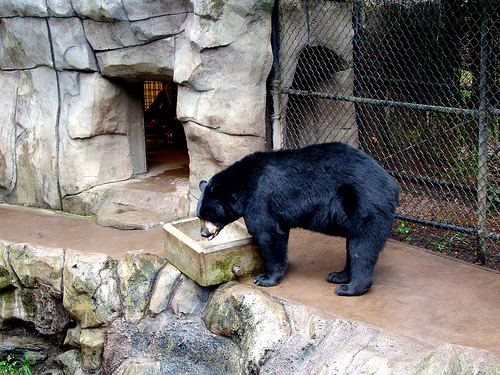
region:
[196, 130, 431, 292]
the bear is black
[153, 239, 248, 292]
the bin is white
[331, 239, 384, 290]
the bear has hind legs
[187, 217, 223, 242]
the bear has a nose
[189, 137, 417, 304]
the bear coat is shiney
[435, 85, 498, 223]
the fence is metal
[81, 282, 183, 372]
the rocks are gray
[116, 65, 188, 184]
the cave is open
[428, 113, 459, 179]
the fence is mesh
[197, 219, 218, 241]
the nose is brown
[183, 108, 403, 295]
this is a bear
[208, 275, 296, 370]
this is a stone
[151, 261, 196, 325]
this is a stone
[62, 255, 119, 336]
this is a stone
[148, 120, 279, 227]
this is a stone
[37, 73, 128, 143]
this is a stone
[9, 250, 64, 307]
this is a stone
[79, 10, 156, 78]
this is a stone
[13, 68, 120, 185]
this is a stone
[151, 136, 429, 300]
black bear drinking water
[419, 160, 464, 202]
chain link fence behind bear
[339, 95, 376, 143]
chain link fence behind bear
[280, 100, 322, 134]
chain link fence behind bear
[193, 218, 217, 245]
black bear's nose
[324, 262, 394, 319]
black bear's large paws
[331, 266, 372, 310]
black bear's large paw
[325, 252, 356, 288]
black bear's large paw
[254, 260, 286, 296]
black bear's large paw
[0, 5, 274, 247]
rocky cave for bear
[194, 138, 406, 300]
Black bear in a zoo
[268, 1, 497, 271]
Chain link fence behind the bear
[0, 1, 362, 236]
Living area for the bear made of rock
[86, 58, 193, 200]
Outside entrance to the rock cave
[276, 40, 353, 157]
Entrance inside the fence for the bear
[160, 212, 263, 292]
Eating box for the bear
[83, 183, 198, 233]
Rock step into the cave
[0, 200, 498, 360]
Concrete walk area for the bear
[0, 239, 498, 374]
Rock area below the bear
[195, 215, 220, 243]
Tan nose on the black bear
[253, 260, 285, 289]
the bear's left front paw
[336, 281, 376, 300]
the bear's left back paw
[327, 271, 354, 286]
the bear's right back paw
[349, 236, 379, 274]
the bear's left back leg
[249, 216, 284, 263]
the bear's left front leg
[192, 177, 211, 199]
the bear's right ear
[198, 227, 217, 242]
the bear's nose and mouth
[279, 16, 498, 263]
chain link fence behind the bear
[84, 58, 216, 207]
entrance to the cave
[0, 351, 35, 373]
top of a green bush